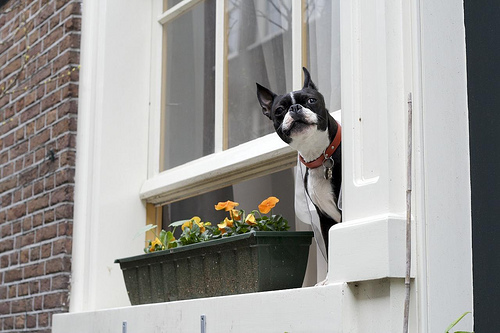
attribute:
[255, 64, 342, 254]
dog — black and white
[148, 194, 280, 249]
flower — yellow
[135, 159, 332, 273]
window — open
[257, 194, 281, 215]
flowers — Orange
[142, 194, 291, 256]
flowers — orange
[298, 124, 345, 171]
collar —  red 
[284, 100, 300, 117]
nose — black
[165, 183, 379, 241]
flowers — orange, ornamental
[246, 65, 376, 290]
dog — looking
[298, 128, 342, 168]
collar — red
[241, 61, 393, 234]
bostan — black 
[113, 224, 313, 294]
planter — black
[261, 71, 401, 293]
dog — black and white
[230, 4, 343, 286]
curtains — white, inside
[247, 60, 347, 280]
dog — black, white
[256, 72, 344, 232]
terrier — white boston